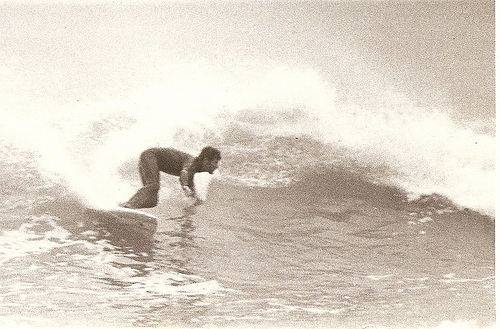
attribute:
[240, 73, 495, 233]
wave — white , crashing 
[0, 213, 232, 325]
foam — white 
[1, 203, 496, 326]
water — calm 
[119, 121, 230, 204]
man — dark haired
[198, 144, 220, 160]
hair — dark 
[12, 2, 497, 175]
spray — ocean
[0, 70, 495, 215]
foam — white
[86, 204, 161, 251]
surfboard — white 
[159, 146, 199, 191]
shirt — long sleeved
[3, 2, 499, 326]
water — brown